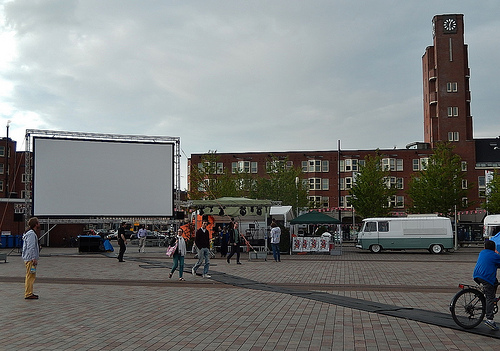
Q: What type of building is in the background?
A: Brick.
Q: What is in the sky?
A: Clouds.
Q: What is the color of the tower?
A: Red.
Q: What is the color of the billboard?
A: White.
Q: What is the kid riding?
A: A bike.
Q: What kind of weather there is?
A: Cloudy.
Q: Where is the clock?
A: On top of the tower.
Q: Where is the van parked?
A: In front of the building.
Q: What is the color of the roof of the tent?
A: Green.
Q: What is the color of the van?
A: White and green.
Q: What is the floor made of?
A: Bricks.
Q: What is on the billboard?
A: The billboard is blank.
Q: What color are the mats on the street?
A: The mats are black in color.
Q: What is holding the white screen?
A: A metal frame.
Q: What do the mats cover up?
A: They cover up cables.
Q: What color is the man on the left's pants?
A: Yellow.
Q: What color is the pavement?
A: Gray.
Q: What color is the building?
A: Brown.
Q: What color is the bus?
A: White.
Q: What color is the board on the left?
A: White.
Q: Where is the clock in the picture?
A: Top Right.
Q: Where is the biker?
A: On the right.